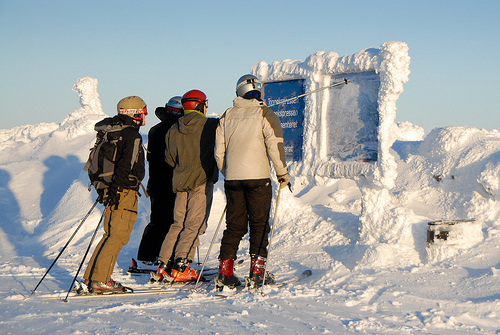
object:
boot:
[249, 253, 275, 285]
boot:
[90, 279, 125, 293]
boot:
[216, 259, 242, 292]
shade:
[311, 203, 364, 244]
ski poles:
[22, 196, 111, 304]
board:
[263, 79, 305, 162]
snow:
[0, 39, 500, 335]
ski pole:
[267, 79, 352, 108]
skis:
[19, 257, 313, 300]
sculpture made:
[250, 41, 432, 272]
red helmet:
[181, 89, 207, 114]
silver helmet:
[235, 73, 262, 97]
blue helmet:
[165, 95, 185, 115]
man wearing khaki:
[82, 95, 148, 295]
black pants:
[216, 178, 271, 260]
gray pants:
[155, 181, 214, 266]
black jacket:
[146, 106, 186, 197]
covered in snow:
[310, 153, 452, 255]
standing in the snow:
[82, 73, 289, 295]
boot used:
[425, 218, 486, 258]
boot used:
[125, 244, 223, 291]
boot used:
[320, 183, 404, 271]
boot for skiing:
[226, 169, 313, 301]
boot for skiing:
[192, 199, 249, 297]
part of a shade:
[66, 154, 86, 175]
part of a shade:
[39, 155, 69, 227]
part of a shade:
[13, 223, 63, 277]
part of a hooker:
[313, 190, 379, 290]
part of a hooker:
[278, 170, 290, 192]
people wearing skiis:
[19, 73, 313, 302]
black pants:
[137, 190, 177, 262]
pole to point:
[349, 77, 356, 83]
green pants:
[82, 188, 139, 284]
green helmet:
[117, 95, 149, 126]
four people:
[82, 73, 291, 295]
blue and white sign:
[261, 69, 381, 163]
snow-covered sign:
[321, 71, 381, 163]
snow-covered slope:
[375, 125, 499, 228]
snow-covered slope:
[314, 164, 425, 297]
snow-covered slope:
[23, 168, 104, 281]